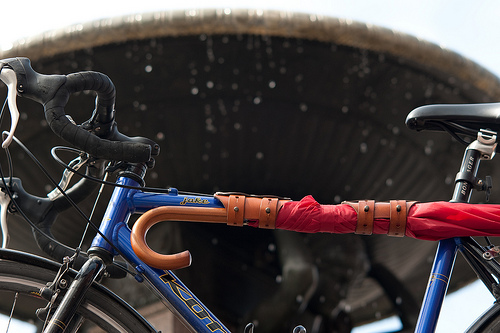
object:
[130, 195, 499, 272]
umbrella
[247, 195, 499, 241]
cloth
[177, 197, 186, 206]
letters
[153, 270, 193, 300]
letters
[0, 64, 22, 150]
brake handle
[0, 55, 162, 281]
handle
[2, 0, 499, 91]
sky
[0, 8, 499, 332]
tunnel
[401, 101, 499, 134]
seat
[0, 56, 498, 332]
bicycle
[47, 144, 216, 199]
wires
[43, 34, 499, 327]
rain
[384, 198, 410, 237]
strap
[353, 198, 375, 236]
strap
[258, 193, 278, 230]
strap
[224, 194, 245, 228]
strap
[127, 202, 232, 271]
handle